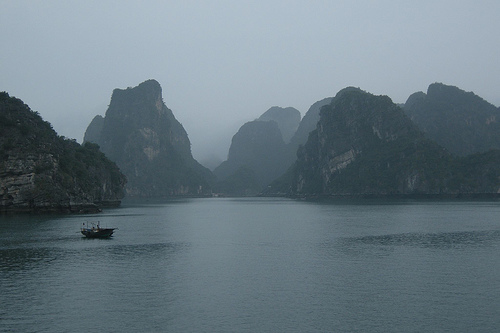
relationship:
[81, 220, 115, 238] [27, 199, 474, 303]
boat in water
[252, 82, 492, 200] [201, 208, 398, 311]
rock in water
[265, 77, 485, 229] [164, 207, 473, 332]
rock in water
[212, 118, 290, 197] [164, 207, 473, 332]
rock in water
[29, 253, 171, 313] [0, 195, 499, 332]
ripples in waves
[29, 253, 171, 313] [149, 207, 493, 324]
ripples in water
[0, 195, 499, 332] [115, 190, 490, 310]
waves in lake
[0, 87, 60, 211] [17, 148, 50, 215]
cliff has rock face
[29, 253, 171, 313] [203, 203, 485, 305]
ripples on water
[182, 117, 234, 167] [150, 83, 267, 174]
mist between hills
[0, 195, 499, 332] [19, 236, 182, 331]
waves with ripples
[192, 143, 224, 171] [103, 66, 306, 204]
valley between hills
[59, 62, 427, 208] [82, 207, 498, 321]
rock on water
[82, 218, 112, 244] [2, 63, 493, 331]
boat travelling area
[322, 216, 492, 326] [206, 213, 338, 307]
waves in water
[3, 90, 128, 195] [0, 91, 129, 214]
trees on rock formation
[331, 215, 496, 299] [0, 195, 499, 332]
ripples on waves